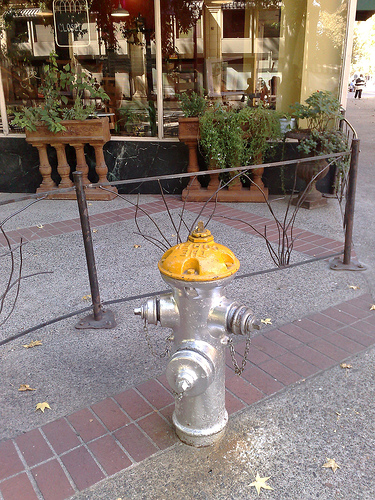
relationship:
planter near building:
[295, 95, 350, 212] [0, 0, 375, 195]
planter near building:
[181, 102, 281, 200] [0, 0, 375, 195]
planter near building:
[20, 72, 115, 197] [0, 0, 375, 195]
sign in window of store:
[52, 5, 114, 48] [36, 6, 374, 162]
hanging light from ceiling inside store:
[109, 4, 131, 17] [1, 0, 373, 191]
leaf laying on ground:
[247, 471, 275, 497] [0, 193, 374, 498]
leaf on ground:
[32, 400, 50, 415] [0, 96, 368, 498]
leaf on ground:
[17, 384, 33, 393] [0, 96, 368, 498]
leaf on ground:
[20, 338, 40, 351] [0, 96, 368, 498]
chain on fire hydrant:
[227, 338, 252, 377] [131, 217, 264, 448]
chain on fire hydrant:
[140, 326, 170, 358] [131, 217, 264, 448]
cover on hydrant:
[158, 221, 241, 282] [133, 271, 265, 447]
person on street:
[341, 52, 374, 99] [6, 95, 371, 495]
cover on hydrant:
[162, 228, 215, 290] [133, 219, 262, 447]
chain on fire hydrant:
[229, 343, 250, 376] [113, 208, 279, 473]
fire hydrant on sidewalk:
[134, 220, 263, 448] [1, 184, 371, 496]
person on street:
[352, 71, 368, 102] [345, 99, 371, 285]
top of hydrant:
[157, 221, 239, 279] [133, 219, 262, 447]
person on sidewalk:
[354, 74, 366, 100] [344, 96, 373, 301]